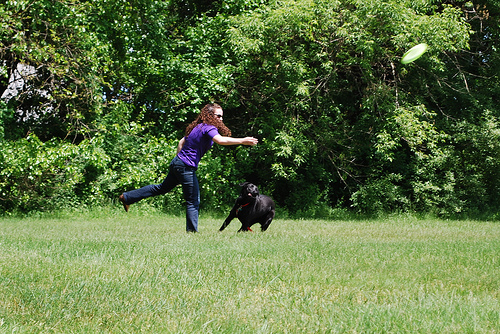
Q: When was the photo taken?
A: During the day.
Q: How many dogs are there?
A: One.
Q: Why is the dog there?
A: To play with the woman.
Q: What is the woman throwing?
A: A frisbee.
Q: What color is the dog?
A: Black.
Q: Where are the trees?
A: Behind the dog.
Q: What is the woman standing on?
A: The grass.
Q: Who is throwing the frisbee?
A: The woman.